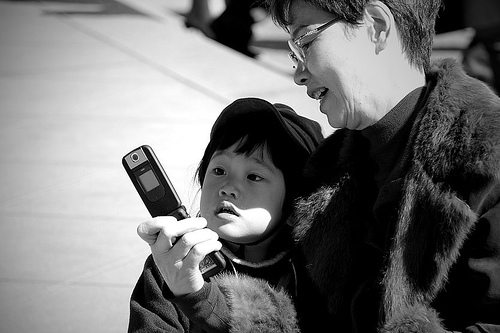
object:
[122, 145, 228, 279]
cellphone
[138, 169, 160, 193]
screen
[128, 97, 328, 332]
girl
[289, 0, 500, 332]
lady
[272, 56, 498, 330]
coat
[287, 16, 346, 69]
glasses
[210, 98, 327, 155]
hat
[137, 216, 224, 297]
hand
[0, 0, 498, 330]
photo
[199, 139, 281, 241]
face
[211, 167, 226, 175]
dark eye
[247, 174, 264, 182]
dark eye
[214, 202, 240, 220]
mouth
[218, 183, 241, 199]
nose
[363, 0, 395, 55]
ear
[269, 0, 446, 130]
head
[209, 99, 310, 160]
brim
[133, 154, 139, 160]
lens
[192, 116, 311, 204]
hair